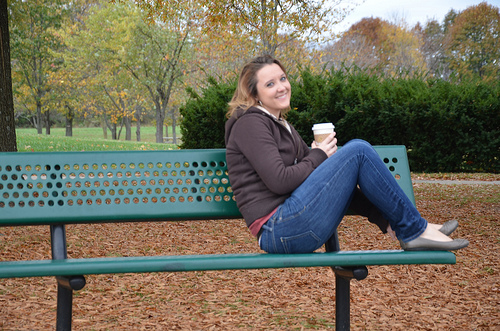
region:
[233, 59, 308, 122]
A woman is smiling.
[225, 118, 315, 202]
A woman is wearing a brown sweater.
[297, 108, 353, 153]
A woman is holding a cup.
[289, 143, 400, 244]
A woman is wearing blue jeans.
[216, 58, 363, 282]
A woman is sitting on a bench.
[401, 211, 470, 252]
A woman is wearing grey flats.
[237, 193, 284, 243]
A woman is wearing a red shirt under sweater.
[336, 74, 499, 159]
Green bushes is located behind the woman.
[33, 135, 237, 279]
The bench is under the woman.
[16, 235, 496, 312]
Leaves are scattered around the bench.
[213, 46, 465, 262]
woman on a bench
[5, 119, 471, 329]
bench at a park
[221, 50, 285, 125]
woman's long brown hair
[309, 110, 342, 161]
coffee cup in woman's hand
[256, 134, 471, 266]
woman's bent legs on a bench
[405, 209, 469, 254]
pair of grey shoes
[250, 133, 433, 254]
woman's blue jeans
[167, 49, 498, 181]
hedge in a park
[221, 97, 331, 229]
grey colored jacket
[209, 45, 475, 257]
woman smiling at the camera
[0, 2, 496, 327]
A woman is outside.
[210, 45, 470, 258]
A woman is sitting on the bench.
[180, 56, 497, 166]
A green bush is in the background.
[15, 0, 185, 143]
Trees are in the distance.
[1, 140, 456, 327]
The bench is made of green metal.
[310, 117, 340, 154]
The woman is holding coffee.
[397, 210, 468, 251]
The woman is wearing grey shoes.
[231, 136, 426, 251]
The woman is wearing jeans.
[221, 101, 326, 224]
The woman is wearing a sweat shirt.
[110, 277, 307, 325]
Leaves are on the ground.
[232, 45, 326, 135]
face of the cute girl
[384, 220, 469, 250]
legs of the girl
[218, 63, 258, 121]
hairs of the cute girl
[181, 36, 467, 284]
a girl sitting in chair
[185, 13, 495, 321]
a hot girls in chair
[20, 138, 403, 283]
a green clean chair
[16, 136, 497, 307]
a long bench in park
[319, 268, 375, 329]
legs of the bench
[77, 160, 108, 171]
small holes in the bench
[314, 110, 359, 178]
a cup holding by girl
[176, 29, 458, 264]
This woman is on a bench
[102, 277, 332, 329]
The ground is covered in leaves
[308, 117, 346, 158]
The woman is holding a coffee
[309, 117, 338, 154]
The coffee is in a paper cup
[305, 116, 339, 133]
The coffee cup has a lid on it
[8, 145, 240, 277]
The bench is made of metal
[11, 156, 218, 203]
The bench has many circular holes in it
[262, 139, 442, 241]
This woman is wearing blue jeans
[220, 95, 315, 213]
She is wearing a brown hooded sweatshirt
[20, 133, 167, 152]
The grass has a few brown leaves on it